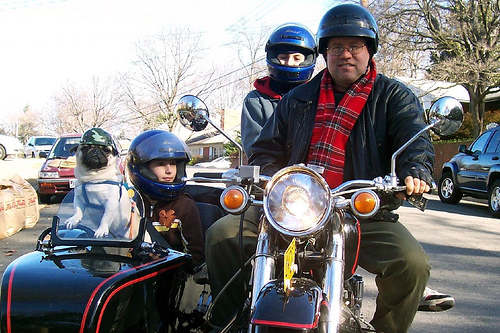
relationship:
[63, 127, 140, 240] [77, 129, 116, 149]
dog with helmet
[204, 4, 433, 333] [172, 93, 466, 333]
man riding motorcycle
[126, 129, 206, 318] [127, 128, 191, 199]
child wearing helmet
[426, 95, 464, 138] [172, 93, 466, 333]
mirror on motorcycle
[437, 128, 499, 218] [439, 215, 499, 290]
suv on street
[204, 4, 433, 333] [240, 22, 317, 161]
man with passenger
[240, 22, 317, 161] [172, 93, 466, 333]
boy on motorcycle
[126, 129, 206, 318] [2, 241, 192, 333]
passenger in sidecar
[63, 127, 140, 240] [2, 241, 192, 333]
dog in sidecar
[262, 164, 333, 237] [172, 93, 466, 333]
headlight on motorcycle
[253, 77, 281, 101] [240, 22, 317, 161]
hoodie on passenger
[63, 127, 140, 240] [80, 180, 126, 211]
dog wearing harness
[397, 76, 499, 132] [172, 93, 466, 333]
house behind motorcycle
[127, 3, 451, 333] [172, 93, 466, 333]
family riding motorcycle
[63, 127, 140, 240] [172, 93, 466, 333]
dog in motorcycle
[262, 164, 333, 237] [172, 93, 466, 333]
headlight of motorcycle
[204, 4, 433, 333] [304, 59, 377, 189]
man wearing scarf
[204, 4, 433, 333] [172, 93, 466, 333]
man on motorcycle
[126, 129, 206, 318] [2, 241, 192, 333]
child in sidecar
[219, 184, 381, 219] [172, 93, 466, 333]
turnsignals of motorcycle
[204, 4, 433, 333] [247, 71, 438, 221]
man with jacket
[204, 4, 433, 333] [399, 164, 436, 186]
man with gloves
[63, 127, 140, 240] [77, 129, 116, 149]
dog wearing helmet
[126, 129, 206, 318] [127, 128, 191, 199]
kid wearing helmet